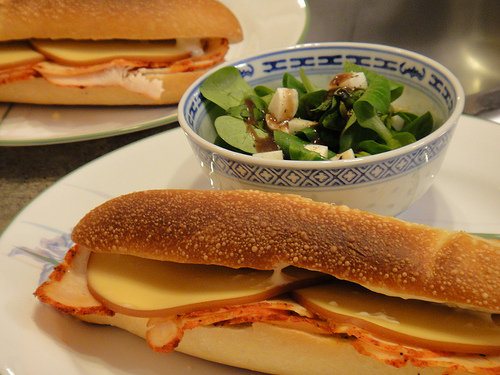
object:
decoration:
[208, 155, 408, 187]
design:
[383, 144, 415, 180]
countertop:
[13, 177, 25, 186]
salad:
[169, 29, 462, 168]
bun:
[85, 192, 499, 314]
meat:
[0, 45, 228, 98]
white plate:
[0, 113, 497, 373]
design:
[247, 171, 402, 185]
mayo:
[262, 264, 291, 283]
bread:
[71, 191, 500, 275]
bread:
[292, 216, 369, 256]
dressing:
[243, 99, 275, 154]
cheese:
[393, 317, 466, 342]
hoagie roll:
[3, 0, 249, 107]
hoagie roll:
[72, 190, 499, 368]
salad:
[196, 58, 425, 168]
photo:
[3, 4, 498, 372]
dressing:
[229, 67, 374, 157]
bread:
[70, 186, 499, 314]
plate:
[62, 179, 74, 186]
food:
[47, 39, 499, 374]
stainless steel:
[429, 27, 496, 101]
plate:
[0, 0, 310, 147]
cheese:
[83, 257, 309, 318]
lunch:
[33, 35, 471, 371]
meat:
[30, 245, 497, 372]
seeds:
[234, 192, 288, 224]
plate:
[48, 72, 465, 370]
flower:
[257, 68, 332, 153]